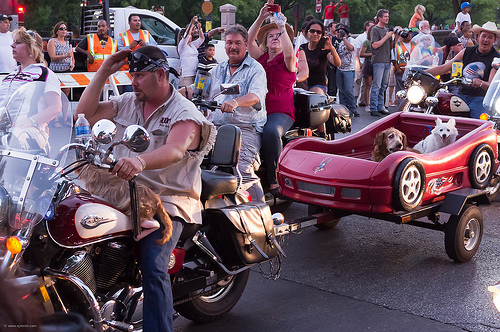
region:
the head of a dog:
[431, 115, 459, 146]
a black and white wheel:
[441, 200, 483, 263]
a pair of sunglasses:
[121, 46, 168, 71]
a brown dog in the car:
[370, 125, 422, 162]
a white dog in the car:
[412, 115, 459, 154]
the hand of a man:
[113, 153, 145, 180]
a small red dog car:
[269, 106, 497, 225]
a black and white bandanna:
[122, 55, 178, 80]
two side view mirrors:
[81, 115, 151, 156]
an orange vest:
[85, 32, 116, 72]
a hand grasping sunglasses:
[104, 45, 157, 74]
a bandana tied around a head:
[129, 51, 174, 75]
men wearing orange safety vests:
[87, 13, 154, 46]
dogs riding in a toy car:
[374, 117, 461, 151]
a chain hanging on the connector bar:
[257, 254, 300, 279]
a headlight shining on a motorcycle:
[405, 78, 430, 114]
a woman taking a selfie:
[251, 4, 306, 80]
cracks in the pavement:
[428, 303, 497, 330]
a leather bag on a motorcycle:
[211, 209, 307, 268]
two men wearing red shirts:
[323, 1, 349, 23]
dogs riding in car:
[365, 116, 474, 179]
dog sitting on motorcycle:
[71, 148, 203, 320]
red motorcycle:
[23, 167, 195, 263]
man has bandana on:
[121, 26, 220, 100]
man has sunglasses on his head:
[101, 11, 187, 109]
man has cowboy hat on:
[468, 11, 496, 33]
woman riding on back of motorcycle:
[216, 11, 393, 157]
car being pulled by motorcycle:
[198, 111, 470, 253]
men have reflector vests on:
[85, 18, 172, 92]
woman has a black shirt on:
[292, 29, 352, 100]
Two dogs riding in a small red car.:
[371, 116, 456, 164]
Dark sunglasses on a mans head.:
[125, 50, 169, 74]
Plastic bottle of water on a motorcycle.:
[75, 112, 95, 159]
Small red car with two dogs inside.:
[277, 110, 499, 210]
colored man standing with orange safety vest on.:
[75, 20, 112, 70]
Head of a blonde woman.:
[8, 25, 43, 71]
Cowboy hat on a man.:
[473, 19, 498, 36]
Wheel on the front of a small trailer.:
[444, 204, 485, 262]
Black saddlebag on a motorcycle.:
[198, 202, 283, 272]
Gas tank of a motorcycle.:
[47, 196, 132, 245]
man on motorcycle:
[0, 32, 241, 324]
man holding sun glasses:
[112, 25, 178, 87]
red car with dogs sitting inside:
[257, 105, 498, 277]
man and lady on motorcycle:
[189, 0, 379, 187]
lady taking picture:
[251, 0, 328, 64]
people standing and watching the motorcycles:
[332, 0, 498, 107]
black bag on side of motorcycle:
[206, 193, 313, 286]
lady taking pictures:
[175, 16, 226, 92]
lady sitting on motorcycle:
[5, 12, 95, 205]